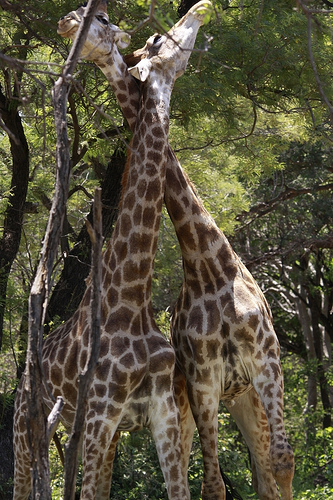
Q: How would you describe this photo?
A: Two giraffes looking up.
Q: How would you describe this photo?
A: Two giraffes looking up.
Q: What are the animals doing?
A: Giraffes looking up.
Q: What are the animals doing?
A: Giraffes looking up.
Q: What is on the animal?
A: Brown fur.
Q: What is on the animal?
A: Brown fur.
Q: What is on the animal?
A: Brown fur.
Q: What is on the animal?
A: Brown fur.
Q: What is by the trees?
A: Giraffe in forest.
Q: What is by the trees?
A: Giraffes in forest.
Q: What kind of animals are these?
A: Giraffes.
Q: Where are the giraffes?
A: Forest.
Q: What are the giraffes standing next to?
A: Trees.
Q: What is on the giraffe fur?
A: Brown spots.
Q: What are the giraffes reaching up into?
A: Trees.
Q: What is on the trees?
A: Leaves.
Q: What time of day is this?
A: Daylight hours.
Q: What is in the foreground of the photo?
A: Tree trunk.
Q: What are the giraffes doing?
A: Grazing trees.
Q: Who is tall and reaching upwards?
A: Two giraffes.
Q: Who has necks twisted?
A: Two giraffes.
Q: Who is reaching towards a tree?
A: A giraffe.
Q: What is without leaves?
A: Two tree trunks.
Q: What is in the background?
A: Vegetation.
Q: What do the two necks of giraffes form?
A: A "X".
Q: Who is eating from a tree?
A: Giraffes.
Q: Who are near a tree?
A: Giraffes.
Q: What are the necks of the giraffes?
A: Long.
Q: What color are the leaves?
A: Green.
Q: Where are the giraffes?
A: In the midst of the trees.